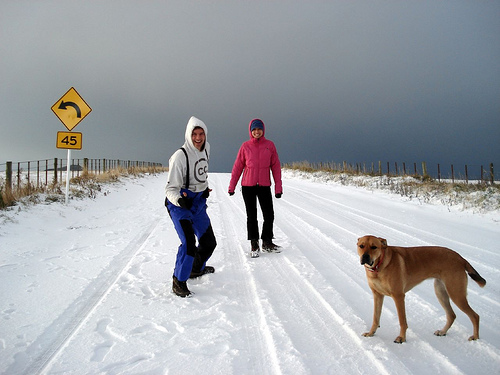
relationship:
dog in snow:
[356, 234, 488, 346] [2, 169, 499, 373]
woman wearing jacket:
[226, 117, 285, 258] [226, 117, 283, 196]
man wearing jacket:
[165, 114, 218, 298] [166, 116, 211, 208]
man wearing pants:
[165, 114, 218, 298] [165, 188, 218, 282]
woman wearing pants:
[226, 117, 285, 258] [242, 184, 275, 242]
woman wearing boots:
[226, 117, 285, 258] [246, 239, 284, 259]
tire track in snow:
[6, 208, 163, 374] [2, 169, 499, 373]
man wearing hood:
[165, 114, 218, 298] [185, 114, 210, 155]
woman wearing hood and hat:
[226, 117, 285, 258] [248, 117, 267, 141]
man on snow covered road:
[165, 115, 217, 297] [1, 165, 498, 374]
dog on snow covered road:
[356, 234, 488, 346] [1, 165, 498, 374]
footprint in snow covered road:
[90, 341, 111, 366] [1, 165, 498, 374]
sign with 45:
[56, 130, 85, 150] [60, 134, 78, 146]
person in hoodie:
[165, 114, 218, 298] [166, 116, 211, 208]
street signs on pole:
[50, 84, 92, 150] [66, 148, 71, 197]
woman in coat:
[226, 117, 285, 258] [226, 117, 283, 196]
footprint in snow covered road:
[96, 316, 114, 335] [1, 165, 498, 374]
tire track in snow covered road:
[250, 255, 347, 373] [1, 165, 498, 374]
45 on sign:
[60, 134, 78, 146] [56, 130, 85, 150]